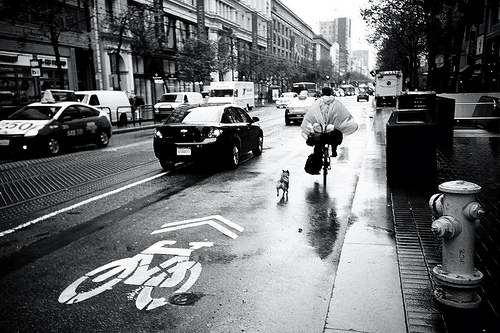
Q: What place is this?
A: It is a street.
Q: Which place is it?
A: It is a street.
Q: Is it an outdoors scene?
A: Yes, it is outdoors.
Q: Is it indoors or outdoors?
A: It is outdoors.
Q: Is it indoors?
A: No, it is outdoors.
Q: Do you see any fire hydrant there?
A: Yes, there is a fire hydrant.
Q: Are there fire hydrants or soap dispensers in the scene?
A: Yes, there is a fire hydrant.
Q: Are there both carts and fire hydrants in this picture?
A: No, there is a fire hydrant but no carts.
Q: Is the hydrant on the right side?
A: Yes, the hydrant is on the right of the image.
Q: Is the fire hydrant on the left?
A: No, the fire hydrant is on the right of the image.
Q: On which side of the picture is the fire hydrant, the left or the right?
A: The fire hydrant is on the right of the image.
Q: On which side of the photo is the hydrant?
A: The hydrant is on the right of the image.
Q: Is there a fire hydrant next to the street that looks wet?
A: Yes, there is a fire hydrant next to the street.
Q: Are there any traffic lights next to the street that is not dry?
A: No, there is a fire hydrant next to the street.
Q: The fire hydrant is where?
A: The fire hydrant is on the sidewalk.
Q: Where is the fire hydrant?
A: The fire hydrant is on the sidewalk.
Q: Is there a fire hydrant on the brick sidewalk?
A: Yes, there is a fire hydrant on the sidewalk.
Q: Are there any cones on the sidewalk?
A: No, there is a fire hydrant on the sidewalk.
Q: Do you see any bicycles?
A: Yes, there is a bicycle.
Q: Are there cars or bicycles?
A: Yes, there is a bicycle.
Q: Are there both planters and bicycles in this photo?
A: No, there is a bicycle but no planters.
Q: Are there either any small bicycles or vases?
A: Yes, there is a small bicycle.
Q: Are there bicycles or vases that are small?
A: Yes, the bicycle is small.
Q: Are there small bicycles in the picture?
A: Yes, there is a small bicycle.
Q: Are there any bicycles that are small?
A: Yes, there is a bicycle that is small.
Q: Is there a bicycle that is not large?
A: Yes, there is a small bicycle.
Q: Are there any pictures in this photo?
A: No, there are no pictures.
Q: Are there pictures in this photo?
A: No, there are no pictures.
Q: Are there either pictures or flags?
A: No, there are no pictures or flags.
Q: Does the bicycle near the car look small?
A: Yes, the bicycle is small.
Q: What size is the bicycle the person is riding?
A: The bicycle is small.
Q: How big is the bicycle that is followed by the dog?
A: The bicycle is small.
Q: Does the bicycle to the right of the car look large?
A: No, the bicycle is small.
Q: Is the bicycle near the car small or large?
A: The bicycle is small.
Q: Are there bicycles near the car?
A: Yes, there is a bicycle near the car.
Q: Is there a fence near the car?
A: No, there is a bicycle near the car.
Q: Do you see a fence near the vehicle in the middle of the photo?
A: No, there is a bicycle near the car.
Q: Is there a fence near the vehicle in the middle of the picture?
A: No, there is a bicycle near the car.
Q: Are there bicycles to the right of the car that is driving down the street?
A: Yes, there is a bicycle to the right of the car.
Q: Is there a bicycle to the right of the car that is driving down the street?
A: Yes, there is a bicycle to the right of the car.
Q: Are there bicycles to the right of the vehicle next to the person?
A: Yes, there is a bicycle to the right of the car.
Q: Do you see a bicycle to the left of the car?
A: No, the bicycle is to the right of the car.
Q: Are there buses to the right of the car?
A: No, there is a bicycle to the right of the car.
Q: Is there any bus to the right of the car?
A: No, there is a bicycle to the right of the car.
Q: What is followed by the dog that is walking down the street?
A: The bicycle is followed by the dog.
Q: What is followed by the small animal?
A: The bicycle is followed by the dog.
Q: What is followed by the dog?
A: The bicycle is followed by the dog.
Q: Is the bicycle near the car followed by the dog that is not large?
A: Yes, the bicycle is followed by the dog.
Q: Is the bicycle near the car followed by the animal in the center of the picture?
A: Yes, the bicycle is followed by the dog.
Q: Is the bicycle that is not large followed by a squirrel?
A: No, the bicycle is followed by the dog.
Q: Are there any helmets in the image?
A: No, there are no helmets.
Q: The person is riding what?
A: The person is riding the bicycle.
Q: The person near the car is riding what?
A: The person is riding the bicycle.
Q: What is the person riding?
A: The person is riding the bicycle.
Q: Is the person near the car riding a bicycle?
A: Yes, the person is riding a bicycle.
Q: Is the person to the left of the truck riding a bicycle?
A: Yes, the person is riding a bicycle.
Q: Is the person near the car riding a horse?
A: No, the person is riding a bicycle.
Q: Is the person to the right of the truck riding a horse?
A: No, the person is riding a bicycle.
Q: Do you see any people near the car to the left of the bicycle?
A: Yes, there is a person near the car.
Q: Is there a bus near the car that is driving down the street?
A: No, there is a person near the car.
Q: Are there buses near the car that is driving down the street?
A: No, there is a person near the car.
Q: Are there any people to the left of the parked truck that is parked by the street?
A: Yes, there is a person to the left of the truck.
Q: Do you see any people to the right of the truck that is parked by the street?
A: No, the person is to the left of the truck.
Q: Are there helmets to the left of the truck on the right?
A: No, there is a person to the left of the truck.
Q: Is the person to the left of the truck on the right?
A: Yes, the person is to the left of the truck.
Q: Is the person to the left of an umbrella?
A: No, the person is to the left of the truck.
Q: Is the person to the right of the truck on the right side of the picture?
A: No, the person is to the left of the truck.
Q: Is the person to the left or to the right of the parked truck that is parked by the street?
A: The person is to the left of the truck.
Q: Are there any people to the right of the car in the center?
A: Yes, there is a person to the right of the car.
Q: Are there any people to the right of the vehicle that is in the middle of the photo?
A: Yes, there is a person to the right of the car.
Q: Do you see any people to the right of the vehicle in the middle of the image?
A: Yes, there is a person to the right of the car.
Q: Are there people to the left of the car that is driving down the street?
A: No, the person is to the right of the car.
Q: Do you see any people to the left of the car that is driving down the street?
A: No, the person is to the right of the car.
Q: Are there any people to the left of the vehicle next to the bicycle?
A: No, the person is to the right of the car.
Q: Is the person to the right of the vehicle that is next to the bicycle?
A: Yes, the person is to the right of the car.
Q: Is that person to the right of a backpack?
A: No, the person is to the right of the car.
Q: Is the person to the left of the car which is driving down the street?
A: No, the person is to the right of the car.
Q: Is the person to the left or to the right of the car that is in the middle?
A: The person is to the right of the car.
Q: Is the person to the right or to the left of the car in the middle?
A: The person is to the right of the car.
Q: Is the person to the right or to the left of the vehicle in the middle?
A: The person is to the right of the car.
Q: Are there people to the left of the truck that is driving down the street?
A: No, the person is to the right of the truck.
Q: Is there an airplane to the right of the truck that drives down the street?
A: No, there is a person to the right of the truck.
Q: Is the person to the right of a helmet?
A: No, the person is to the right of the truck.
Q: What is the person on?
A: The person is on the bicycle.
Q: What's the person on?
A: The person is on the bicycle.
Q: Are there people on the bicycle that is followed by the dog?
A: Yes, there is a person on the bicycle.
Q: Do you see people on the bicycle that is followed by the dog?
A: Yes, there is a person on the bicycle.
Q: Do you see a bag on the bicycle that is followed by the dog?
A: No, there is a person on the bicycle.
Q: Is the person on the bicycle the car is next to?
A: Yes, the person is on the bicycle.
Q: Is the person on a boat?
A: No, the person is on the bicycle.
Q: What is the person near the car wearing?
A: The person is wearing a raincoat.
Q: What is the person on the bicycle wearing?
A: The person is wearing a raincoat.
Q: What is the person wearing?
A: The person is wearing a raincoat.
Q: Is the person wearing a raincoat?
A: Yes, the person is wearing a raincoat.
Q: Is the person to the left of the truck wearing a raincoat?
A: Yes, the person is wearing a raincoat.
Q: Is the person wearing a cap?
A: No, the person is wearing a raincoat.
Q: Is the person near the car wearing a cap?
A: No, the person is wearing a raincoat.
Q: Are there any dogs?
A: Yes, there is a dog.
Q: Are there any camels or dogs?
A: Yes, there is a dog.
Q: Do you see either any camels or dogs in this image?
A: Yes, there is a dog.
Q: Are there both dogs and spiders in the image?
A: No, there is a dog but no spiders.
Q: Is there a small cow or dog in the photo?
A: Yes, there is a small dog.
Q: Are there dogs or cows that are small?
A: Yes, the dog is small.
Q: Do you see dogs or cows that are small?
A: Yes, the dog is small.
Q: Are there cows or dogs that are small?
A: Yes, the dog is small.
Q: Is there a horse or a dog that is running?
A: Yes, the dog is running.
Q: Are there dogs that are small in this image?
A: Yes, there is a small dog.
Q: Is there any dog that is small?
A: Yes, there is a dog that is small.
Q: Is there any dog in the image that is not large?
A: Yes, there is a small dog.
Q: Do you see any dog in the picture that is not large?
A: Yes, there is a small dog.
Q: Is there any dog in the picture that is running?
A: Yes, there is a dog that is running.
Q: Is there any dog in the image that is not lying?
A: Yes, there is a dog that is running.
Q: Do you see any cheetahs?
A: No, there are no cheetahs.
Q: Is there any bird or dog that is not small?
A: No, there is a dog but it is small.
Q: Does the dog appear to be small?
A: Yes, the dog is small.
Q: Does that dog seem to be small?
A: Yes, the dog is small.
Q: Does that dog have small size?
A: Yes, the dog is small.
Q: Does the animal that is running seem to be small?
A: Yes, the dog is small.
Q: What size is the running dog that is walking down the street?
A: The dog is small.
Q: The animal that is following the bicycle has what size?
A: The dog is small.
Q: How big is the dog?
A: The dog is small.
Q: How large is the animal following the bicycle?
A: The dog is small.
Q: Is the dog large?
A: No, the dog is small.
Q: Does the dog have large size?
A: No, the dog is small.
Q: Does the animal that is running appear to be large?
A: No, the dog is small.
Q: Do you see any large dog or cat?
A: No, there is a dog but it is small.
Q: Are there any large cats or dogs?
A: No, there is a dog but it is small.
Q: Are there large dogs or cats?
A: No, there is a dog but it is small.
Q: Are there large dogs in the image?
A: No, there is a dog but it is small.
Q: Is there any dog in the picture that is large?
A: No, there is a dog but it is small.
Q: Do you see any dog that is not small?
A: No, there is a dog but it is small.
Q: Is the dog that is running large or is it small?
A: The dog is small.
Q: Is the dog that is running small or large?
A: The dog is small.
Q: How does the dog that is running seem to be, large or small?
A: The dog is small.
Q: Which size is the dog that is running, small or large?
A: The dog is small.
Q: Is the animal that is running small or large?
A: The dog is small.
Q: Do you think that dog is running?
A: Yes, the dog is running.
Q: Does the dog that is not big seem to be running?
A: Yes, the dog is running.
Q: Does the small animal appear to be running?
A: Yes, the dog is running.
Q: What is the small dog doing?
A: The dog is running.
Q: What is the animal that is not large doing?
A: The dog is running.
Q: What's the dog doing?
A: The dog is running.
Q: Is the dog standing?
A: No, the dog is running.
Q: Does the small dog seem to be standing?
A: No, the dog is running.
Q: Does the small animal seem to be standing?
A: No, the dog is running.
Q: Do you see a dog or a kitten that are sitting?
A: No, there is a dog but it is running.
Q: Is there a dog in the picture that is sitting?
A: No, there is a dog but it is running.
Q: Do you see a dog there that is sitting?
A: No, there is a dog but it is running.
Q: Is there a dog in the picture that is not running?
A: No, there is a dog but it is running.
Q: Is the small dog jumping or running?
A: The dog is running.